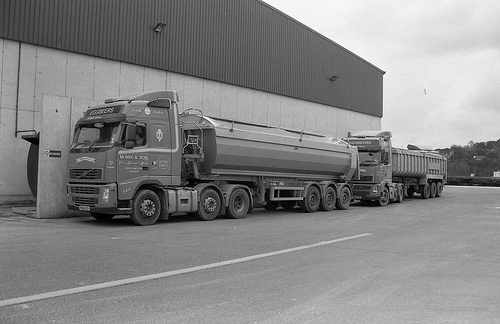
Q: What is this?
A: Truck.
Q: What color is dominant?
A: Gray.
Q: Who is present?
A: No one.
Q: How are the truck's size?
A: Huge.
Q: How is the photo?
A: Clear.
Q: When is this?
A: Daytime.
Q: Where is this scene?
A: Alongside an industrial building.